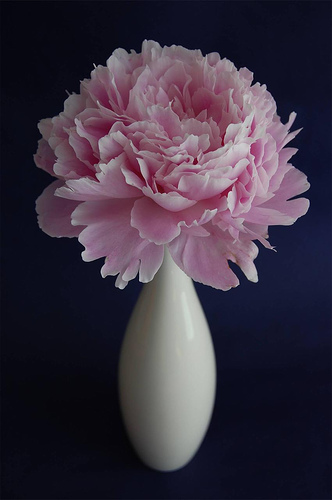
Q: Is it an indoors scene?
A: Yes, it is indoors.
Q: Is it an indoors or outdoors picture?
A: It is indoors.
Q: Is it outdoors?
A: No, it is indoors.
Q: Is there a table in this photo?
A: Yes, there is a table.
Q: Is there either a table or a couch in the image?
A: Yes, there is a table.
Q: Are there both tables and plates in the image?
A: No, there is a table but no plates.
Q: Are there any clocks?
A: No, there are no clocks.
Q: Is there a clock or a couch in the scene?
A: No, there are no clocks or couches.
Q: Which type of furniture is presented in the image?
A: The furniture is a table.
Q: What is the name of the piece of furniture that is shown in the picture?
A: The piece of furniture is a table.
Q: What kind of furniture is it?
A: The piece of furniture is a table.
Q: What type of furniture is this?
A: That is a table.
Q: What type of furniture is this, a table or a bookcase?
A: That is a table.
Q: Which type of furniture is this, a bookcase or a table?
A: That is a table.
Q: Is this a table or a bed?
A: This is a table.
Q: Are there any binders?
A: No, there are no binders.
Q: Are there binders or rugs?
A: No, there are no binders or rugs.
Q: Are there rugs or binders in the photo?
A: No, there are no binders or rugs.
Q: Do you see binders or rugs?
A: No, there are no binders or rugs.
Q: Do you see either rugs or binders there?
A: No, there are no binders or rugs.